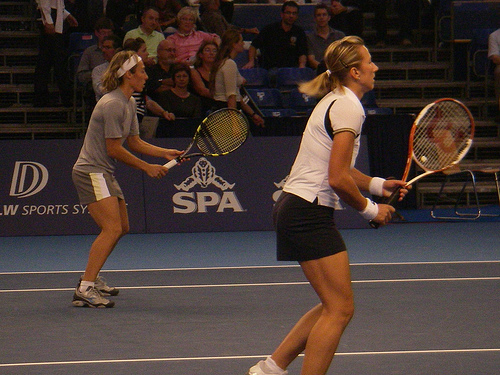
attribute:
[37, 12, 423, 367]
women — playing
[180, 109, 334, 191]
racket — yellow, black, tennis racket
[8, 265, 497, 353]
lines — white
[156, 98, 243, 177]
racket — yellow, black, tennis racket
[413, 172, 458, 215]
ground — yellow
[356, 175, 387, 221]
wrist sweatbands — white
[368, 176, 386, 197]
wrist sweatband — white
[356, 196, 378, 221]
wrist sweatband — white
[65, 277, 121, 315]
shoes — gray, black, athletic shoes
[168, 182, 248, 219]
word spa — white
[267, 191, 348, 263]
shorts — black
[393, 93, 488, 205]
racket — white, red, tennis racket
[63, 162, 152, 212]
shorts — gray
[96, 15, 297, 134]
crowd — small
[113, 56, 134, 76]
headband — white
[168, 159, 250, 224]
advertisements — blue, white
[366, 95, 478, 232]
racket — red, white, tennis racket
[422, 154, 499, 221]
chair — empty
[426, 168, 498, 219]
legs — silver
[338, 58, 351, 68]
clip — black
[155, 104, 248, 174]
racket — black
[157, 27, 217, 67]
shirt — pink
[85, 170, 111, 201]
stripe — white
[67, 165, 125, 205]
skirt — white, gray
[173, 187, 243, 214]
spa — word, letters, white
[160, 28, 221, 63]
shirt — pink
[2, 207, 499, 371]
court — blue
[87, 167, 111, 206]
stripe — white